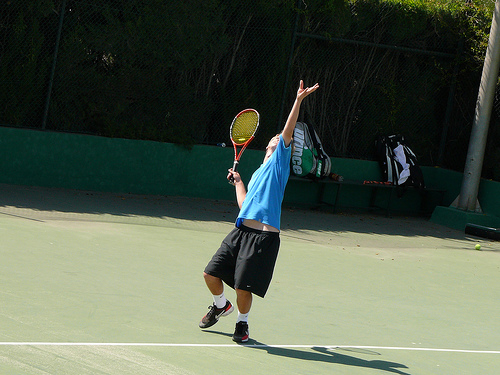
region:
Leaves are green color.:
[360, 2, 463, 37]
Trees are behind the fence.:
[267, 10, 447, 91]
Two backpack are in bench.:
[290, 118, 442, 190]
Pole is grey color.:
[468, 87, 491, 203]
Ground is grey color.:
[35, 240, 125, 305]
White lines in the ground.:
[30, 307, 266, 368]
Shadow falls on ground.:
[42, 183, 422, 371]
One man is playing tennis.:
[202, 86, 317, 347]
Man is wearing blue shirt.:
[241, 160, 284, 227]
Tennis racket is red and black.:
[221, 106, 264, 185]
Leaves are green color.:
[392, 6, 484, 46]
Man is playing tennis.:
[213, 93, 297, 330]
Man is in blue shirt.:
[234, 150, 304, 234]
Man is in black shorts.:
[201, 223, 283, 289]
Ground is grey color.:
[326, 264, 474, 322]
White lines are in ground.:
[156, 308, 488, 367]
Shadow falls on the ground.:
[106, 188, 410, 373]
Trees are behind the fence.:
[100, 23, 477, 172]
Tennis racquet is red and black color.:
[224, 104, 264, 186]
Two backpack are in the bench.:
[288, 117, 430, 185]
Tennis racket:
[219, 98, 263, 158]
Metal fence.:
[2, 4, 439, 110]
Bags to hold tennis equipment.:
[288, 117, 436, 186]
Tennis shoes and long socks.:
[196, 291, 261, 351]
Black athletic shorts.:
[198, 218, 290, 300]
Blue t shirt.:
[229, 145, 313, 230]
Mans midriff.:
[224, 211, 293, 237]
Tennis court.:
[5, 181, 483, 373]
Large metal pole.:
[459, 13, 498, 215]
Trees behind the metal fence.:
[13, 0, 490, 130]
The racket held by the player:
[222, 104, 261, 187]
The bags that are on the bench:
[294, 97, 419, 190]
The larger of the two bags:
[292, 101, 339, 183]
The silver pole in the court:
[448, 1, 499, 218]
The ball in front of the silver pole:
[466, 236, 490, 254]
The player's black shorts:
[200, 221, 289, 298]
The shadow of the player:
[207, 326, 410, 373]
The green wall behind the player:
[0, 126, 495, 221]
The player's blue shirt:
[234, 137, 302, 234]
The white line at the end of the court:
[0, 339, 499, 356]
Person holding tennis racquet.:
[200, 105, 316, 301]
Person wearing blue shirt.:
[238, 152, 302, 221]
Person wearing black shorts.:
[214, 266, 279, 304]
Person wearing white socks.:
[206, 282, 277, 357]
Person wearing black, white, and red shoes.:
[193, 292, 277, 372]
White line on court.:
[102, 321, 329, 368]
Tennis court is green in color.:
[68, 212, 178, 362]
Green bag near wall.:
[296, 132, 338, 228]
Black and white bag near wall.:
[367, 115, 428, 214]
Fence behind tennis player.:
[38, 107, 249, 147]